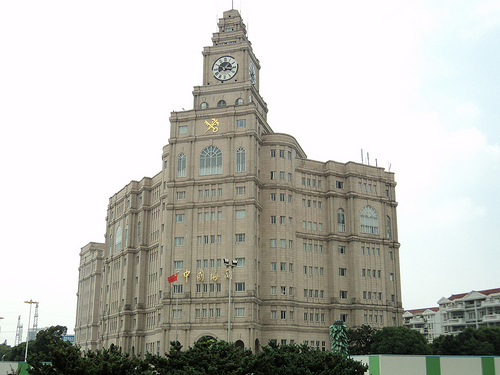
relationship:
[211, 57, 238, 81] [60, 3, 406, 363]
clock on building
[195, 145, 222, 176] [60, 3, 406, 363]
windows on building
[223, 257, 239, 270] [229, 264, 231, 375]
street light on pole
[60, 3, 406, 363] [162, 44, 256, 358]
building has front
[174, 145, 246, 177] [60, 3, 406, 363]
windows on building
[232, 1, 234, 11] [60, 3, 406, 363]
antenna on building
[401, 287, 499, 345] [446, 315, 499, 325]
apartment building has balconies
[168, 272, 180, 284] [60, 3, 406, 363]
flag in front building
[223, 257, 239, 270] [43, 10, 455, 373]
street light in front building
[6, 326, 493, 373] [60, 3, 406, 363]
bushes in front building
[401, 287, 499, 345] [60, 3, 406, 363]
apartment building behind building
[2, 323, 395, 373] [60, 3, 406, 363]
trees in front of building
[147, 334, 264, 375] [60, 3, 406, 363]
trees at base of building